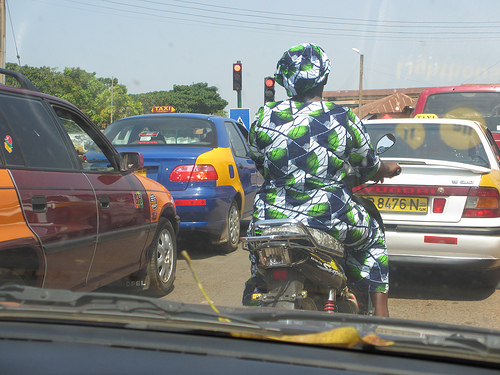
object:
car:
[82, 111, 269, 254]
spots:
[194, 146, 245, 215]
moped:
[238, 131, 400, 314]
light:
[262, 76, 276, 106]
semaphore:
[265, 90, 276, 103]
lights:
[231, 60, 241, 91]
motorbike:
[239, 132, 402, 313]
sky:
[0, 0, 495, 42]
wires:
[85, 0, 496, 40]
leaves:
[51, 69, 121, 94]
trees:
[91, 83, 145, 129]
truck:
[401, 83, 499, 151]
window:
[423, 91, 500, 133]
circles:
[263, 79, 275, 87]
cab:
[358, 117, 499, 289]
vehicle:
[80, 105, 264, 254]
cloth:
[272, 43, 331, 97]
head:
[271, 42, 331, 99]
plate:
[360, 191, 429, 214]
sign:
[148, 105, 175, 114]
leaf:
[208, 298, 396, 368]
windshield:
[99, 114, 221, 148]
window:
[0, 88, 79, 172]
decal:
[4, 134, 14, 155]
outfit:
[245, 42, 391, 295]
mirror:
[375, 132, 397, 155]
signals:
[232, 63, 242, 73]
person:
[239, 42, 402, 318]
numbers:
[365, 197, 420, 214]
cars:
[0, 67, 180, 304]